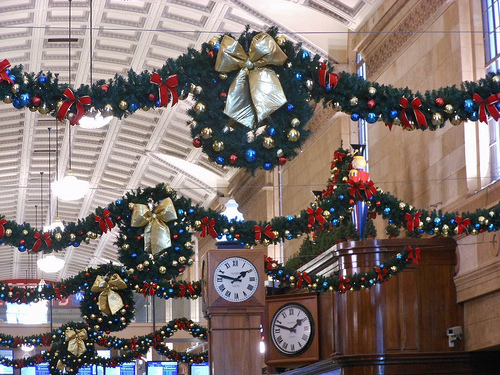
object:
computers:
[57, 182, 419, 364]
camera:
[445, 326, 463, 348]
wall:
[456, 226, 497, 356]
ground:
[413, 100, 431, 150]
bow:
[213, 31, 288, 131]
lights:
[43, 217, 65, 235]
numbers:
[216, 260, 256, 299]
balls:
[367, 89, 377, 97]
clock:
[213, 256, 260, 303]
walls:
[365, 55, 470, 206]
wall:
[290, 120, 464, 209]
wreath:
[0, 35, 217, 127]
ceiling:
[2, 1, 170, 59]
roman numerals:
[289, 309, 294, 316]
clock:
[269, 301, 315, 357]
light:
[78, 107, 115, 130]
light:
[50, 170, 91, 201]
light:
[36, 256, 66, 275]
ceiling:
[0, 0, 244, 283]